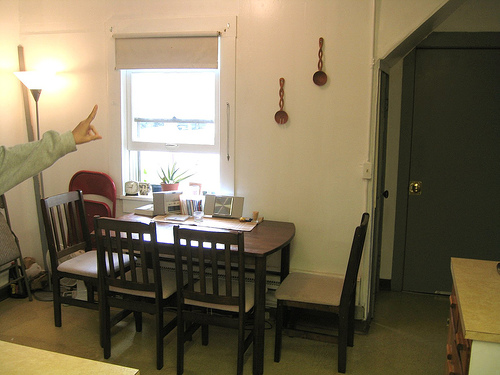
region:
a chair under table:
[187, 219, 274, 344]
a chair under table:
[276, 220, 380, 372]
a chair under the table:
[90, 215, 127, 337]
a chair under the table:
[26, 183, 133, 309]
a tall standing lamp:
[7, 49, 113, 211]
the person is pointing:
[27, 75, 135, 139]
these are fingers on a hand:
[54, 88, 111, 155]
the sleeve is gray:
[1, 113, 82, 203]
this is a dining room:
[50, 164, 224, 314]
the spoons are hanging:
[261, 17, 403, 188]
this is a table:
[102, 147, 310, 309]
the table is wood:
[158, 205, 253, 273]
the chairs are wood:
[78, 204, 266, 331]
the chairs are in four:
[57, 203, 367, 373]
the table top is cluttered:
[121, 168, 225, 242]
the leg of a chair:
[332, 313, 350, 373]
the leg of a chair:
[274, 296, 290, 358]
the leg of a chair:
[236, 318, 261, 373]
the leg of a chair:
[248, 304, 268, 365]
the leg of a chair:
[177, 311, 188, 373]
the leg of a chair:
[157, 310, 169, 367]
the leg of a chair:
[103, 296, 115, 357]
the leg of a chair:
[131, 303, 148, 335]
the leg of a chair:
[51, 263, 68, 330]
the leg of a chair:
[86, 278, 104, 298]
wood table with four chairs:
[27, 195, 369, 372]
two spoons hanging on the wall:
[272, 36, 328, 125]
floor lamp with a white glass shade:
[10, 70, 52, 276]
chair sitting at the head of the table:
[270, 210, 362, 342]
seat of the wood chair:
[271, 265, 341, 310]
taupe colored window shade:
[110, 25, 220, 66]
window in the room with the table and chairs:
[117, 27, 214, 194]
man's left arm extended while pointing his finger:
[0, 101, 100, 196]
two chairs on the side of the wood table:
[85, 213, 256, 359]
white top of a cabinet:
[0, 337, 136, 372]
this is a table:
[102, 175, 308, 372]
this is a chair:
[266, 208, 396, 365]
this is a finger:
[76, 99, 106, 129]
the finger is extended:
[65, 90, 117, 151]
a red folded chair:
[63, 148, 125, 248]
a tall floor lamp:
[16, 45, 80, 299]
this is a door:
[363, 13, 498, 333]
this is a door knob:
[399, 173, 424, 202]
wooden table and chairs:
[31, 158, 417, 374]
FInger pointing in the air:
[55, 103, 105, 147]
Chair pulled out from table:
[270, 209, 371, 373]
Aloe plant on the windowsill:
[153, 159, 190, 208]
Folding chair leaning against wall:
[65, 168, 117, 278]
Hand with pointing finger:
[68, 98, 100, 153]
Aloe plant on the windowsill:
[154, 154, 191, 201]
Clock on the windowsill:
[123, 175, 138, 200]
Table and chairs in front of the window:
[34, 188, 369, 373]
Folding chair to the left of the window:
[63, 167, 118, 247]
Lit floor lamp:
[13, 63, 61, 293]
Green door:
[397, 50, 498, 297]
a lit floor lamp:
[16, 71, 61, 301]